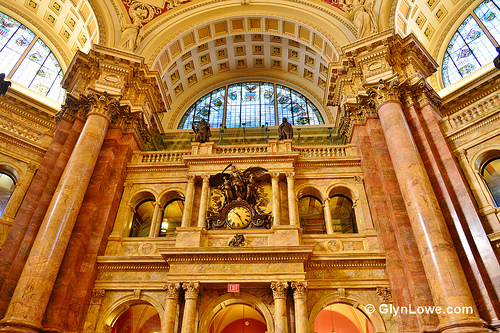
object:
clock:
[226, 205, 252, 229]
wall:
[106, 143, 409, 333]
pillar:
[0, 91, 147, 333]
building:
[0, 0, 500, 333]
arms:
[232, 211, 245, 225]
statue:
[192, 117, 294, 143]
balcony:
[97, 225, 385, 262]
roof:
[0, 0, 500, 132]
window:
[176, 81, 322, 130]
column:
[350, 90, 497, 333]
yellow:
[149, 0, 385, 88]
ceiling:
[144, 16, 345, 126]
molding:
[54, 0, 170, 152]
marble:
[362, 89, 454, 221]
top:
[132, 0, 357, 69]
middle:
[80, 127, 398, 333]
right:
[355, 72, 461, 283]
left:
[0, 105, 140, 333]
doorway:
[207, 297, 267, 332]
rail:
[130, 218, 355, 237]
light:
[161, 206, 169, 233]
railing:
[142, 144, 348, 163]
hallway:
[218, 311, 265, 333]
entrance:
[218, 317, 268, 333]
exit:
[228, 284, 240, 293]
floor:
[95, 202, 384, 258]